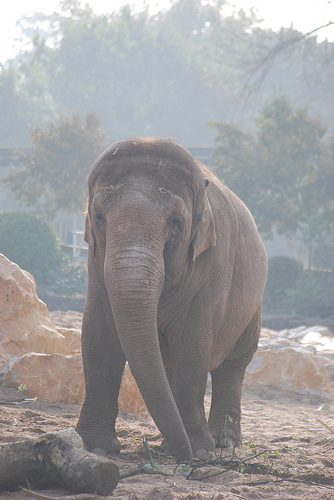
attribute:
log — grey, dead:
[0, 427, 118, 495]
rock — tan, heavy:
[241, 338, 332, 399]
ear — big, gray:
[190, 169, 216, 262]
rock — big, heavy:
[241, 345, 333, 397]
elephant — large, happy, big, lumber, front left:
[74, 137, 267, 464]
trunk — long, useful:
[104, 197, 193, 462]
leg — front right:
[165, 281, 214, 461]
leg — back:
[208, 307, 260, 447]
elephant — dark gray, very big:
[79, 142, 267, 441]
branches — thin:
[155, 428, 300, 478]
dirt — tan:
[253, 400, 333, 451]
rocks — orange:
[0, 259, 85, 396]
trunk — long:
[95, 240, 200, 465]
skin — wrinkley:
[180, 201, 258, 340]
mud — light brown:
[193, 453, 278, 492]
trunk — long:
[106, 244, 197, 468]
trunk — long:
[103, 232, 198, 456]